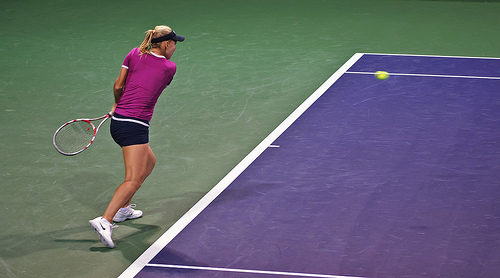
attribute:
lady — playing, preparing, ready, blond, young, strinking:
[87, 22, 180, 229]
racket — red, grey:
[52, 112, 105, 159]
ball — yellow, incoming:
[373, 69, 389, 81]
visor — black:
[173, 29, 186, 43]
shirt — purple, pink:
[129, 55, 168, 119]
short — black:
[111, 124, 145, 145]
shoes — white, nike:
[92, 218, 117, 248]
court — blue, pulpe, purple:
[324, 84, 493, 276]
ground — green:
[0, 0, 52, 276]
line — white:
[338, 63, 348, 78]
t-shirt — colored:
[129, 59, 155, 125]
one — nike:
[98, 220, 109, 232]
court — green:
[9, 6, 499, 27]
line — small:
[270, 144, 280, 149]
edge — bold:
[334, 62, 349, 80]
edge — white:
[107, 118, 150, 126]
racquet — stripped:
[50, 108, 105, 160]